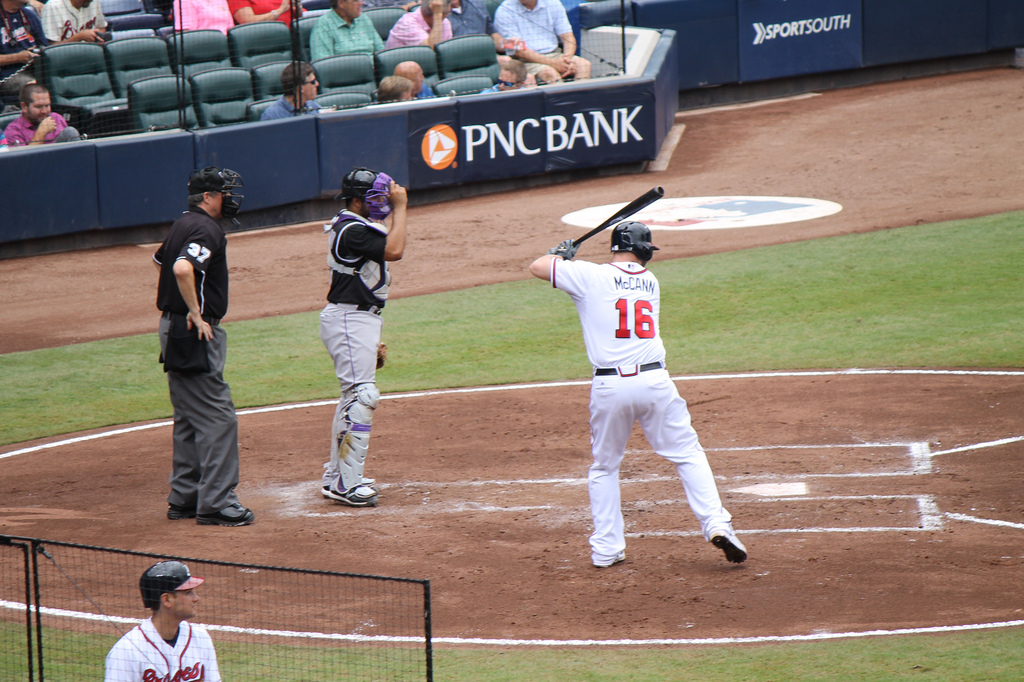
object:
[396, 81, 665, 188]
advertisement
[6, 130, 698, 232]
wall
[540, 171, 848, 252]
emblems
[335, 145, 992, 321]
ground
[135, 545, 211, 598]
hat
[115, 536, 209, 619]
head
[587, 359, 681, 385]
belt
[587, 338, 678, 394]
waist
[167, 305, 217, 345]
hands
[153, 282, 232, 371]
hip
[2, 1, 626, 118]
fans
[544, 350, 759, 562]
pants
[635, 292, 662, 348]
number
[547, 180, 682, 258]
bat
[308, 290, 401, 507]
pants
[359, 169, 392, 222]
mask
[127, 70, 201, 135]
chair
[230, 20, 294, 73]
chair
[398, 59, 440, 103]
person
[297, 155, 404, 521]
catcher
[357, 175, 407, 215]
face mask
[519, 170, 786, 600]
baseball player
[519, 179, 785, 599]
man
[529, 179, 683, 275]
baseball bat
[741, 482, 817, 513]
home plate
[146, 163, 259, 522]
umpire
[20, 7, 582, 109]
spectators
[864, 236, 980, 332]
grass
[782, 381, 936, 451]
dirt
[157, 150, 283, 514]
umpire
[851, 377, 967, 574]
dirt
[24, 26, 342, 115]
seats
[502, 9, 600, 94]
person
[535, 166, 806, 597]
player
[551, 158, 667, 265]
bat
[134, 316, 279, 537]
pants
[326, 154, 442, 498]
catcher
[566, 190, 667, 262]
bat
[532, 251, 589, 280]
gloves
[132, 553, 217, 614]
helmet